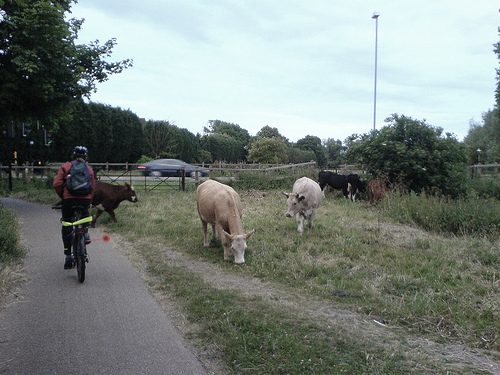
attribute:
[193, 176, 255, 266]
cow — tan, grazing, grazing by road, brown, eating grass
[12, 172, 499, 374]
foliage — green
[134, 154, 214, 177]
car — dark gray, running, blue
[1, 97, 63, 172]
house — in background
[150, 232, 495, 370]
path — worn in grass, in grass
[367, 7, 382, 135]
pole — for light, tall, gray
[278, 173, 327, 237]
cow — looking at biker, walking, standing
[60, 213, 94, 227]
reflection mark — yellow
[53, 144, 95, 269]
person — biking, riding bicycle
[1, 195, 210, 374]
biking path — concrete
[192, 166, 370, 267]
cows — grazing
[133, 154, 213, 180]
sedan — on road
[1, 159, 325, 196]
fence — short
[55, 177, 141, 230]
cow — brown, crossing road, white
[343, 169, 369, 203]
cow — grazing, black, white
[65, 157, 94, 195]
backpack — blue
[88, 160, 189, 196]
gate — black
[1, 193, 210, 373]
path — for bikes, cows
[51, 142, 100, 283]
cyclist — passing farm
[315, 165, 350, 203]
cow — black